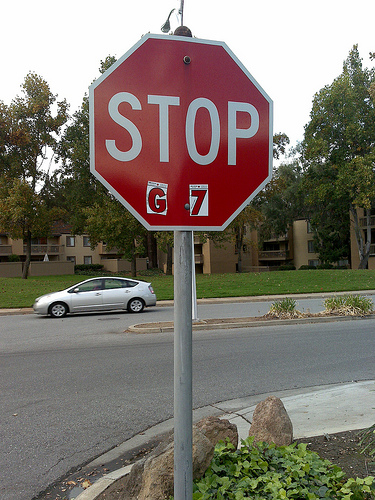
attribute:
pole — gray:
[172, 229, 193, 497]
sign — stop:
[88, 31, 274, 231]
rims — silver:
[47, 299, 83, 321]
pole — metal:
[161, 227, 202, 498]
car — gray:
[31, 273, 156, 318]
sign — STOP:
[109, 38, 261, 182]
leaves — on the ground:
[48, 468, 102, 494]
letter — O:
[188, 97, 219, 165]